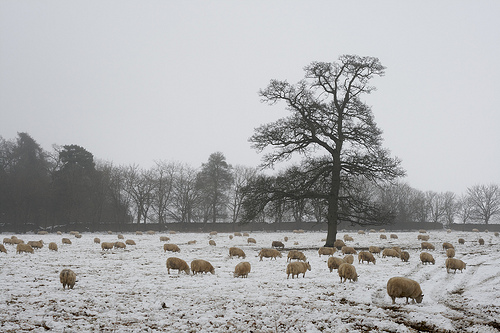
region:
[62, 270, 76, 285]
white sheep in snow covered field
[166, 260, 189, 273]
white sheep in snow covered field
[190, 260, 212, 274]
white sheep in snow covered field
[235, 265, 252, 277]
white sheep in snow covered field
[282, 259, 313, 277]
white sheep in snow covered field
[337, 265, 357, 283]
white sheep in snow covered field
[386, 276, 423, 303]
white sheep in snow covered field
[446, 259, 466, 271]
white sheep in snow covered field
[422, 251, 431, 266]
white sheep in snow covered field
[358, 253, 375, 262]
white sheep in snow covered field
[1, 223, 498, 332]
new snow is in the field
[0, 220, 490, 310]
many sheep are grazing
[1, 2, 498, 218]
the sky is cloudy or foggy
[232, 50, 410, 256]
the large tree in in the field has no leaves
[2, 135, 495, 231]
the trees on the field's edge are leafless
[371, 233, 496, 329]
tire tracks mark a vehicles passage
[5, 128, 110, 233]
the evergreens have not lost their needles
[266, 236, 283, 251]
this sheep is grazing in the tree's shadow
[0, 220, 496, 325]
the snow is fresh but not deep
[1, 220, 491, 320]
the sheep dig through the snow to find browse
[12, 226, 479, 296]
a herd of sheep in a field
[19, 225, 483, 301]
a herd of sheep in a snow covered field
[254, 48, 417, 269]
a bare tree in the field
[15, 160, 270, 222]
a line of bare trees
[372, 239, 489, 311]
tracks in the snow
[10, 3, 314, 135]
a gray sky above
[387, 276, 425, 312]
a sheep grazing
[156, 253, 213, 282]
a couple of sheep grazing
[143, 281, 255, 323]
a snow covered field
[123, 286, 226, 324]
snow and grass in the field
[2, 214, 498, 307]
sheep in a snowy field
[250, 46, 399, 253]
solitary tree in the middle of the field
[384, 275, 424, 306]
a sheep grazing in the snow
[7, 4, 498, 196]
gray featureless sky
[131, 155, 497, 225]
row of windbreak trees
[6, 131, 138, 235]
two large trees at the edge of the field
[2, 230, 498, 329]
a snowy field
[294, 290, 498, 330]
dirt peeking out from under the snow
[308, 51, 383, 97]
the topmost branches of a tree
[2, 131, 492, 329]
snowy winter day for sheep in a field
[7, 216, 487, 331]
field covered in layer of snow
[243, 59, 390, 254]
tree in field covered in snow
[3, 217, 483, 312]
herd of many sheep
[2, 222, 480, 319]
group of sheep grazing in snowy field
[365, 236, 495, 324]
tire tracks in snow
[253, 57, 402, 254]
tree with no leaves on branches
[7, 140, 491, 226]
line of trees on back of field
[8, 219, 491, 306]
white sheep in field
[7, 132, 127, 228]
trees with leaves on left side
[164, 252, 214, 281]
two sheep standing together grazing